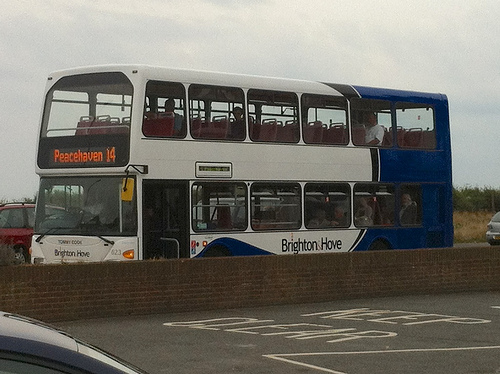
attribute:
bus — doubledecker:
[25, 59, 460, 264]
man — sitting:
[150, 98, 183, 136]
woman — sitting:
[224, 105, 245, 142]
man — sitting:
[362, 112, 389, 147]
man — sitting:
[396, 191, 418, 227]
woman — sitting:
[355, 193, 374, 230]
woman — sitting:
[308, 203, 328, 230]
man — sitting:
[326, 204, 349, 232]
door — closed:
[142, 175, 192, 264]